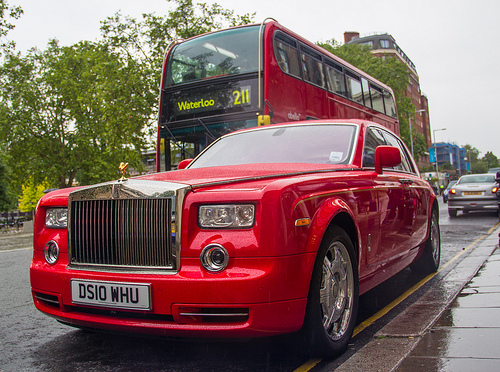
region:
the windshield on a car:
[186, 86, 390, 188]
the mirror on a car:
[352, 137, 428, 190]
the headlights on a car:
[35, 174, 295, 261]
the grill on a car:
[57, 158, 199, 281]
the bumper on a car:
[18, 227, 317, 347]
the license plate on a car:
[46, 258, 168, 328]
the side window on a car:
[354, 96, 461, 180]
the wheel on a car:
[264, 203, 396, 346]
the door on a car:
[345, 135, 447, 284]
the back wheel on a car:
[384, 180, 476, 287]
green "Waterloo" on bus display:
[173, 99, 217, 112]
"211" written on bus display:
[230, 85, 251, 105]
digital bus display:
[165, 87, 255, 114]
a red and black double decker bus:
[153, 15, 400, 170]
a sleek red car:
[31, 118, 440, 355]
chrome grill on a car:
[66, 180, 181, 275]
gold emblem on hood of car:
[118, 159, 128, 174]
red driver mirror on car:
[372, 143, 401, 173]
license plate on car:
[68, 278, 152, 311]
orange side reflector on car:
[293, 215, 309, 227]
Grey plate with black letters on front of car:
[66, 276, 156, 311]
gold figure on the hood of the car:
[114, 158, 128, 183]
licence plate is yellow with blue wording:
[460, 187, 485, 197]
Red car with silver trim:
[29, 121, 440, 351]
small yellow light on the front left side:
[290, 210, 315, 236]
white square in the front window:
[327, 149, 344, 167]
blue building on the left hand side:
[435, 138, 470, 173]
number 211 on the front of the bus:
[228, 81, 250, 108]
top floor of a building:
[348, 31, 420, 70]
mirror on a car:
[370, 142, 407, 170]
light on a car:
[191, 195, 256, 238]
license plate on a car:
[60, 275, 150, 315]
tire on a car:
[305, 231, 365, 354]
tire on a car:
[422, 200, 444, 265]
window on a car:
[200, 127, 345, 170]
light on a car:
[440, 180, 465, 210]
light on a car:
[485, 178, 497, 198]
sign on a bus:
[164, 89, 270, 112]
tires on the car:
[301, 231, 375, 355]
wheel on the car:
[301, 225, 367, 357]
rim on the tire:
[325, 245, 348, 336]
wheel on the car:
[421, 212, 443, 271]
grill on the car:
[68, 185, 175, 267]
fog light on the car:
[41, 242, 59, 261]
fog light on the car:
[197, 240, 227, 269]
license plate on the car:
[65, 274, 151, 310]